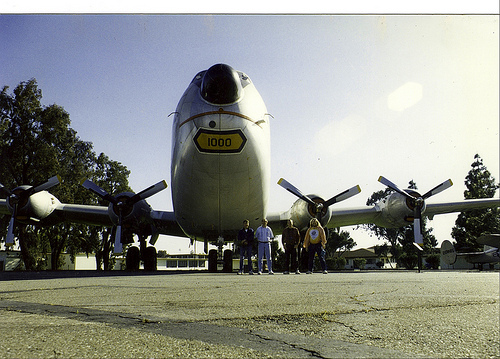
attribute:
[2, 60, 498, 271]
plane — silver, large, parked, standing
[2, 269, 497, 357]
flooring — green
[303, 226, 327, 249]
shirt — yellow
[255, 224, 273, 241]
shirt — plaid, white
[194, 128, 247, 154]
plaque — yellow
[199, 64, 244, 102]
nose — black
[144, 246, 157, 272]
tire — black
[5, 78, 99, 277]
tree — growing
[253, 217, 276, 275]
man — dressed, standing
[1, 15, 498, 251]
sky — hazy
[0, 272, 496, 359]
concrete — cracked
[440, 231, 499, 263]
airplane — small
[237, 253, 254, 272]
jeans — blue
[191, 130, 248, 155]
sign — yellow